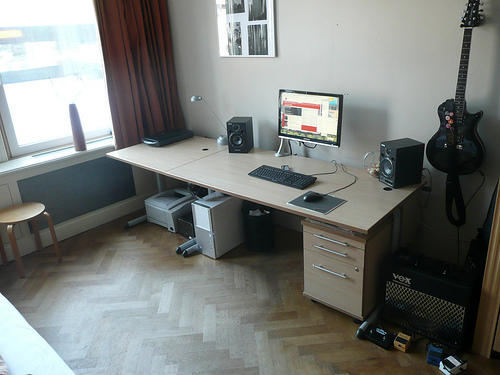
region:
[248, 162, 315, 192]
a black computer keyboard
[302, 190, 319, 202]
a black computer mouse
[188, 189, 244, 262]
a white and silver computer tower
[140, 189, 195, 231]
a white laser printer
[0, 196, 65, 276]
a small brown stool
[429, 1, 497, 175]
a black guitar on wall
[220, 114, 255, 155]
a black computer speaker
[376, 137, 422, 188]
a black computer speaker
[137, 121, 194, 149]
a flatbed desktop scanner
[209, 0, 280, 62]
a framed print on wall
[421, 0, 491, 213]
guitar on the wall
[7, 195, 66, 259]
small wooden stool on ground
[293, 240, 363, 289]
three silver handles on drawers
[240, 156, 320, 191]
a black key board and wire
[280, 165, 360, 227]
a balck mouse and wire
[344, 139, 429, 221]
a black speaker on desk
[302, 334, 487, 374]
amppedals on the floor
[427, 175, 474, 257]
guitar strap lloop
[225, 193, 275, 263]
black trash can with garbage in it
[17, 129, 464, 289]
a desk and guitar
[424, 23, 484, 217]
a guitar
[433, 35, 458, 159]
a guitar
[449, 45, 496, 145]
a guitar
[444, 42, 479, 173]
a guitar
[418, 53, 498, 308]
a guitar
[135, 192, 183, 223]
the printer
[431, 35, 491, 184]
A black guitar on the wall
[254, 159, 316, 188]
a black keyboard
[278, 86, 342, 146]
A computer screen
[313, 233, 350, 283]
Three grey handles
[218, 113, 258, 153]
A black speaker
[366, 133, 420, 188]
A black speaker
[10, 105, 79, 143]
A window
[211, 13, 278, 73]
A picture hanging on the wall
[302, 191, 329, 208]
A black mouse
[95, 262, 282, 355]
a smooth brown floor.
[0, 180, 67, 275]
a small maple color stool.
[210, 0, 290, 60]
a black and white picture on the wall.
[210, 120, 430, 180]
a set of black speakers.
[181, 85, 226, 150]
a lamp on the desk.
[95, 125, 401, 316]
a beige stand.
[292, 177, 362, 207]
a black mouse.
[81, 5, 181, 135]
a brown curtain.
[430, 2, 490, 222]
a black guitar with red and white buttons.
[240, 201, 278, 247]
a small garbage can under the desk.